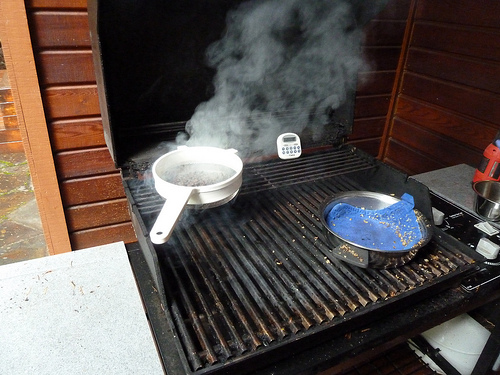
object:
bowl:
[316, 190, 438, 270]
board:
[0, 239, 162, 375]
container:
[407, 309, 499, 374]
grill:
[124, 145, 499, 373]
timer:
[276, 132, 303, 160]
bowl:
[148, 143, 247, 246]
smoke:
[125, 0, 389, 218]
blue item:
[327, 191, 424, 255]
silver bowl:
[470, 175, 499, 222]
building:
[3, 0, 499, 251]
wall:
[0, 0, 499, 252]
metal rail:
[163, 276, 205, 371]